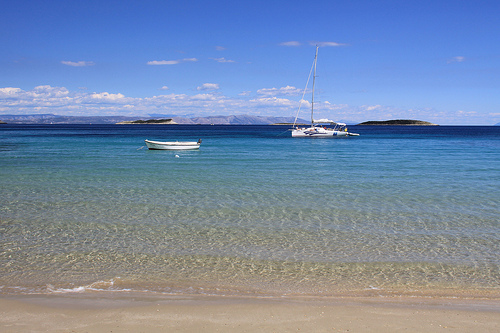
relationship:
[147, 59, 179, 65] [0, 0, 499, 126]
cloud in sky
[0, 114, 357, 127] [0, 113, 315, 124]
horizon on horizon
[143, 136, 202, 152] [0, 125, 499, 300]
boat in water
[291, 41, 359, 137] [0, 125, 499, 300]
base in water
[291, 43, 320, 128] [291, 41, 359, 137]
line on base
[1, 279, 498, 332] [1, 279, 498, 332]
beach on beach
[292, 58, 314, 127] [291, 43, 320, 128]
line on line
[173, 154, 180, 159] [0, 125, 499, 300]
disturbance in water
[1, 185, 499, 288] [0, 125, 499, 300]
riddles in water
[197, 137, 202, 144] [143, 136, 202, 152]
engine on back of boat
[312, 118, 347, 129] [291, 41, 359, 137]
canopy over base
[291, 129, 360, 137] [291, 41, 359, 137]
base of base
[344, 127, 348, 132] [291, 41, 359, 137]
person on base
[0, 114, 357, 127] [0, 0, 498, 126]
horizon in background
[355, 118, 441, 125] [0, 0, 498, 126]
island in background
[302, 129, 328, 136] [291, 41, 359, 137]
design on base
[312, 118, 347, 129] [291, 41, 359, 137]
canopy on base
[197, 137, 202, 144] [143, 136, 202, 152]
engine on boat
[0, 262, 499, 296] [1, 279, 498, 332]
water on shoreline